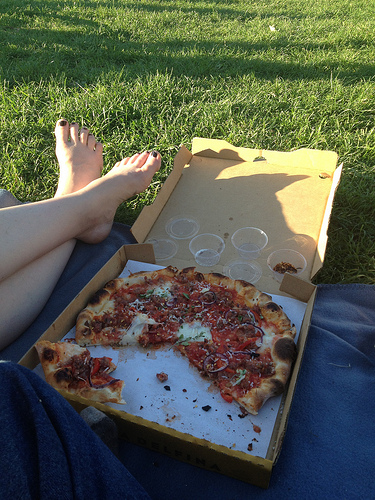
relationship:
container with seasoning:
[232, 227, 271, 259] [275, 260, 298, 271]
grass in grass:
[1, 5, 372, 124] [1, 5, 372, 160]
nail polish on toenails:
[60, 121, 66, 125] [53, 115, 106, 142]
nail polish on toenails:
[150, 151, 156, 157] [115, 148, 171, 161]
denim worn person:
[2, 394, 74, 480] [3, 363, 80, 498]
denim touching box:
[2, 394, 74, 480] [17, 258, 312, 459]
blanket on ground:
[0, 187, 374, 497] [2, 2, 374, 494]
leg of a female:
[7, 113, 150, 292] [1, 84, 111, 255]